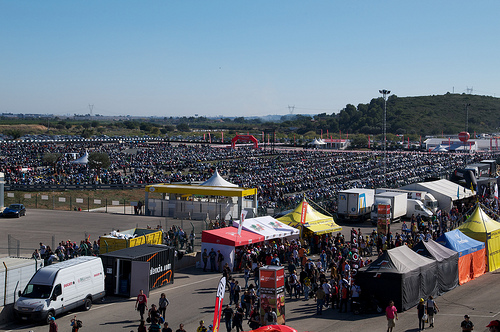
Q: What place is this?
A: It is a road.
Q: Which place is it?
A: It is a road.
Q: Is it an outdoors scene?
A: Yes, it is outdoors.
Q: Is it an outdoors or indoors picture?
A: It is outdoors.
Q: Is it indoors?
A: No, it is outdoors.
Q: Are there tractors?
A: No, there are no tractors.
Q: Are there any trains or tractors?
A: No, there are no tractors or trains.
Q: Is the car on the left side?
A: Yes, the car is on the left of the image.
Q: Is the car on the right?
A: No, the car is on the left of the image.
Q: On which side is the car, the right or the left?
A: The car is on the left of the image.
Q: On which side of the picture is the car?
A: The car is on the left of the image.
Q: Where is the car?
A: The car is on the parking lot.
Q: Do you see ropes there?
A: No, there are no ropes.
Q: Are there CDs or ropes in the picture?
A: No, there are no ropes or cds.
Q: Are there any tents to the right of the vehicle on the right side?
A: Yes, there is a tent to the right of the truck.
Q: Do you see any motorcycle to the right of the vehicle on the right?
A: No, there is a tent to the right of the truck.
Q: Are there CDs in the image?
A: No, there are no cds.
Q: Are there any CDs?
A: No, there are no cds.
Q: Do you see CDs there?
A: No, there are no cds.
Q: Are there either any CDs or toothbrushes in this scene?
A: No, there are no CDs or toothbrushes.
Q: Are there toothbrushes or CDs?
A: No, there are no CDs or toothbrushes.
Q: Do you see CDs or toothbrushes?
A: No, there are no CDs or toothbrushes.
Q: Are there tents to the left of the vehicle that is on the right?
A: Yes, there is a tent to the left of the truck.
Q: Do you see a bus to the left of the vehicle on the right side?
A: No, there is a tent to the left of the truck.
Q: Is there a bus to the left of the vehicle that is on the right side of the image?
A: No, there is a tent to the left of the truck.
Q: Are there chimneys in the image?
A: No, there are no chimneys.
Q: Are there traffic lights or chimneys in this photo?
A: No, there are no chimneys or traffic lights.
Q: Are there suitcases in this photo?
A: No, there are no suitcases.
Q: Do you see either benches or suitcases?
A: No, there are no suitcases or benches.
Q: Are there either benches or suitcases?
A: No, there are no suitcases or benches.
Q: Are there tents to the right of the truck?
A: Yes, there is a tent to the right of the truck.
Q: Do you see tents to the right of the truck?
A: Yes, there is a tent to the right of the truck.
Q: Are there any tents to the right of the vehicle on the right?
A: Yes, there is a tent to the right of the truck.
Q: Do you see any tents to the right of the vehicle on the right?
A: Yes, there is a tent to the right of the truck.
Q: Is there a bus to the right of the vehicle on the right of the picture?
A: No, there is a tent to the right of the truck.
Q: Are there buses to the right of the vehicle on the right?
A: No, there is a tent to the right of the truck.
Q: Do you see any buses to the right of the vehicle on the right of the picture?
A: No, there is a tent to the right of the truck.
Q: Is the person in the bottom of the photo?
A: Yes, the person is in the bottom of the image.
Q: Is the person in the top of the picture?
A: No, the person is in the bottom of the image.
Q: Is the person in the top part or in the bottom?
A: The person is in the bottom of the image.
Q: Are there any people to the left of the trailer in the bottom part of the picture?
A: No, the person is to the right of the trailer.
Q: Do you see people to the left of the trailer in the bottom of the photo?
A: No, the person is to the right of the trailer.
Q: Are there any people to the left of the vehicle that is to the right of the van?
A: No, the person is to the right of the trailer.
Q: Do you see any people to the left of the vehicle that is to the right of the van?
A: No, the person is to the right of the trailer.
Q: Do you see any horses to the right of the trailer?
A: No, there is a person to the right of the trailer.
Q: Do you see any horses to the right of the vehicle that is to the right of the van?
A: No, there is a person to the right of the trailer.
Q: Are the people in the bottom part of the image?
A: Yes, the people are in the bottom of the image.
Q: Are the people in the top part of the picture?
A: No, the people are in the bottom of the image.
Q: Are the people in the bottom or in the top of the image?
A: The people are in the bottom of the image.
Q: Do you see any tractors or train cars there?
A: No, there are no tractors or train cars.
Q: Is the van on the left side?
A: Yes, the van is on the left of the image.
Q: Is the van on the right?
A: No, the van is on the left of the image.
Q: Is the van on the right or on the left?
A: The van is on the left of the image.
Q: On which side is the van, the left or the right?
A: The van is on the left of the image.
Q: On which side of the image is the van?
A: The van is on the left of the image.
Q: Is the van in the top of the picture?
A: No, the van is in the bottom of the image.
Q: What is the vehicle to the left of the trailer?
A: The vehicle is a van.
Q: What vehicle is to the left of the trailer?
A: The vehicle is a van.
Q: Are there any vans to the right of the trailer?
A: No, the van is to the left of the trailer.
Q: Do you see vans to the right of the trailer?
A: No, the van is to the left of the trailer.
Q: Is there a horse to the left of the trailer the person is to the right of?
A: No, there is a van to the left of the trailer.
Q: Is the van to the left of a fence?
A: No, the van is to the left of the trailer.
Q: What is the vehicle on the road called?
A: The vehicle is a van.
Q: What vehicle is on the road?
A: The vehicle is a van.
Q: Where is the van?
A: The van is on the road.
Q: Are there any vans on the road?
A: Yes, there is a van on the road.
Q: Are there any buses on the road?
A: No, there is a van on the road.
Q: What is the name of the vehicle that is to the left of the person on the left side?
A: The vehicle is a van.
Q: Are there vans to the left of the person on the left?
A: Yes, there is a van to the left of the person.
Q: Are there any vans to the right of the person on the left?
A: No, the van is to the left of the person.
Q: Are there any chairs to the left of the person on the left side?
A: No, there is a van to the left of the person.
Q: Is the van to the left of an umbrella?
A: No, the van is to the left of the person.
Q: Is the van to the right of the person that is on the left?
A: No, the van is to the left of the person.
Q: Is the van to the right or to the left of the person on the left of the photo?
A: The van is to the left of the person.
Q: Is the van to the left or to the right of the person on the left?
A: The van is to the left of the person.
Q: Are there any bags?
A: No, there are no bags.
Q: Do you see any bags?
A: No, there are no bags.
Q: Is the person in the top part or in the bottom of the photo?
A: The person is in the bottom of the image.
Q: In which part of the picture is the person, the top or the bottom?
A: The person is in the bottom of the image.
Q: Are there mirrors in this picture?
A: No, there are no mirrors.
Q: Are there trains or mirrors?
A: No, there are no mirrors or trains.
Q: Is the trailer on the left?
A: Yes, the trailer is on the left of the image.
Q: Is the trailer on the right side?
A: No, the trailer is on the left of the image.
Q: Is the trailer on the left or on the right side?
A: The trailer is on the left of the image.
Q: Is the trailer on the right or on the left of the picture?
A: The trailer is on the left of the image.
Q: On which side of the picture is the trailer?
A: The trailer is on the left of the image.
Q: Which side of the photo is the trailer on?
A: The trailer is on the left of the image.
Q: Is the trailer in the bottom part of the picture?
A: Yes, the trailer is in the bottom of the image.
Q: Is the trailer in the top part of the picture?
A: No, the trailer is in the bottom of the image.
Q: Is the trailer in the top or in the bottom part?
A: The trailer is in the bottom of the image.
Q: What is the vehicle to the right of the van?
A: The vehicle is a trailer.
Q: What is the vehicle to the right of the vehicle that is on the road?
A: The vehicle is a trailer.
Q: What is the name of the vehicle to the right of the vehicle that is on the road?
A: The vehicle is a trailer.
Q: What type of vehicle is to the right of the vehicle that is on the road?
A: The vehicle is a trailer.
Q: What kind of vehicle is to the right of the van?
A: The vehicle is a trailer.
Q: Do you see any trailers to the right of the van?
A: Yes, there is a trailer to the right of the van.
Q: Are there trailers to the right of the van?
A: Yes, there is a trailer to the right of the van.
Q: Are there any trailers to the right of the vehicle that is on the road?
A: Yes, there is a trailer to the right of the van.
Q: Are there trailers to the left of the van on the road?
A: No, the trailer is to the right of the van.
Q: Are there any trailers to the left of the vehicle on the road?
A: No, the trailer is to the right of the van.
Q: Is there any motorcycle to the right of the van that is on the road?
A: No, there is a trailer to the right of the van.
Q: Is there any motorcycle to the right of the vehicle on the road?
A: No, there is a trailer to the right of the van.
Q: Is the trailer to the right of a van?
A: Yes, the trailer is to the right of a van.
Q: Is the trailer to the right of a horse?
A: No, the trailer is to the right of a van.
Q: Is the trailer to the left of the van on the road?
A: No, the trailer is to the right of the van.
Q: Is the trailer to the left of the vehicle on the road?
A: No, the trailer is to the right of the van.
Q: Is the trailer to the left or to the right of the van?
A: The trailer is to the right of the van.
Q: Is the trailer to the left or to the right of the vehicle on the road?
A: The trailer is to the right of the van.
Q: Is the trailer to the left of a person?
A: Yes, the trailer is to the left of a person.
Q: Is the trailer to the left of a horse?
A: No, the trailer is to the left of a person.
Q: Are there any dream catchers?
A: No, there are no dream catchers.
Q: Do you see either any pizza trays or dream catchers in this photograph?
A: No, there are no dream catchers or pizza trays.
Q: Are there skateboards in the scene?
A: No, there are no skateboards.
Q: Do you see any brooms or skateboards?
A: No, there are no skateboards or brooms.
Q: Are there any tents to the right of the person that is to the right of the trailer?
A: Yes, there is a tent to the right of the person.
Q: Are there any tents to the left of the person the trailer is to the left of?
A: No, the tent is to the right of the person.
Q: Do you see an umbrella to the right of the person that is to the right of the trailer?
A: No, there is a tent to the right of the person.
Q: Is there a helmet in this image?
A: No, there are no helmets.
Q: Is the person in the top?
A: No, the person is in the bottom of the image.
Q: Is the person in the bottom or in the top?
A: The person is in the bottom of the image.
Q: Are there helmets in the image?
A: No, there are no helmets.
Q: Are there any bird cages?
A: No, there are no bird cages.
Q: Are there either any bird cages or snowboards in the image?
A: No, there are no bird cages or snowboards.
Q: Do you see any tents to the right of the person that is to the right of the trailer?
A: Yes, there is a tent to the right of the person.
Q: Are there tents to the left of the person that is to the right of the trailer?
A: No, the tent is to the right of the person.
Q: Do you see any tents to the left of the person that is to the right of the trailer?
A: No, the tent is to the right of the person.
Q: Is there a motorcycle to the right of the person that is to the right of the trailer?
A: No, there is a tent to the right of the person.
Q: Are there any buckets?
A: No, there are no buckets.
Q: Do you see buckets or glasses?
A: No, there are no buckets or glasses.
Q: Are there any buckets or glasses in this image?
A: No, there are no buckets or glasses.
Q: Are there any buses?
A: No, there are no buses.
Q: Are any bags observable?
A: No, there are no bags.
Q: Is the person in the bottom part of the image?
A: Yes, the person is in the bottom of the image.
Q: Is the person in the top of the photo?
A: No, the person is in the bottom of the image.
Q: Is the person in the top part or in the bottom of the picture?
A: The person is in the bottom of the image.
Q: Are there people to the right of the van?
A: Yes, there is a person to the right of the van.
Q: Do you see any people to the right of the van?
A: Yes, there is a person to the right of the van.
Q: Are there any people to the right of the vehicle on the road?
A: Yes, there is a person to the right of the van.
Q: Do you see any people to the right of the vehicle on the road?
A: Yes, there is a person to the right of the van.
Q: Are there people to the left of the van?
A: No, the person is to the right of the van.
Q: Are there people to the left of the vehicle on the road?
A: No, the person is to the right of the van.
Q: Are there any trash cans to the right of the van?
A: No, there is a person to the right of the van.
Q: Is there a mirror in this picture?
A: No, there are no mirrors.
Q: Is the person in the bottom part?
A: Yes, the person is in the bottom of the image.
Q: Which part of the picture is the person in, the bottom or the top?
A: The person is in the bottom of the image.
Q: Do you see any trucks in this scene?
A: Yes, there is a truck.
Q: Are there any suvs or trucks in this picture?
A: Yes, there is a truck.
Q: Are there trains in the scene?
A: No, there are no trains.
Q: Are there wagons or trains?
A: No, there are no trains or wagons.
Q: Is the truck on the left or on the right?
A: The truck is on the right of the image.